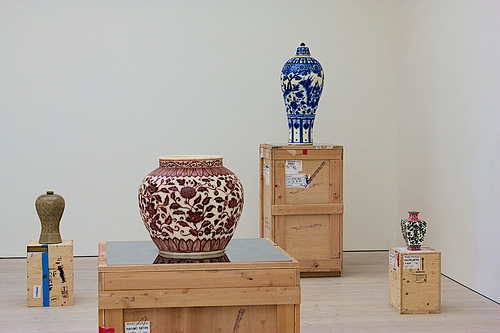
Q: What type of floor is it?
A: Wood.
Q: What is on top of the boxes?
A: Vases.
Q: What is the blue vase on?
A: Box.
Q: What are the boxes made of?
A: Wood.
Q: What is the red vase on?
A: Slick surface.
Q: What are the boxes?
A: Crates.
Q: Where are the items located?
A: In a room.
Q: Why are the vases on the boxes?
A: For spectating.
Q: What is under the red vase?
A: Mirror.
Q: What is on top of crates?
A: Pottery.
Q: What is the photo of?
A: A collection of vases.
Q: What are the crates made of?
A: Wood.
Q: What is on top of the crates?
A: Reflecting glass.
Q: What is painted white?
A: The wall.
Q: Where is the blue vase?
A: On a crate.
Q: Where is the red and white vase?
A: On a crate.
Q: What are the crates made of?
A: Wood.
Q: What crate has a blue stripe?
A: The one on the left.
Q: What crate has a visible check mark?
A: The one holding the blue and white vase.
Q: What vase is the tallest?
A: The blue and white one.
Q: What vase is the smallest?
A: The one on the right.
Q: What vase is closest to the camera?
A: The red and white one.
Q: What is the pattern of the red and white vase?
A: Floral.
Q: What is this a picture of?
A: Vases.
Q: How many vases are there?
A: 4.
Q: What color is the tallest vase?
A: Blue.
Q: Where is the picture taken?
A: In a museum.